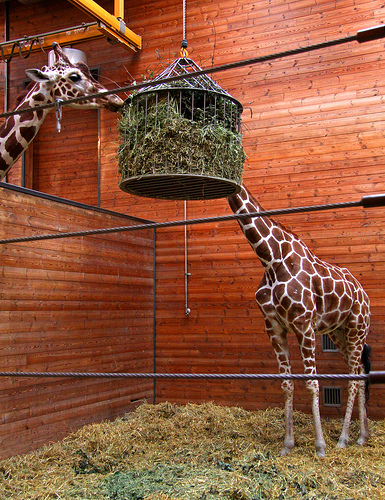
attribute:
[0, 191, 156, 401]
wall — wooden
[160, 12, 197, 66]
rope — large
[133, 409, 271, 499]
hay — brown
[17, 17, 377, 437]
pen — orange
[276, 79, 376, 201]
background — orange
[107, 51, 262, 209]
basket — metal, black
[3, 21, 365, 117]
fence — metal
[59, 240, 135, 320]
walls — brown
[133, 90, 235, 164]
grass — green